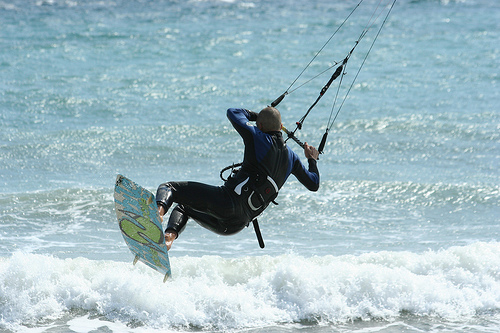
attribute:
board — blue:
[106, 153, 182, 290]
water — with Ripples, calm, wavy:
[361, 110, 478, 222]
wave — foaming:
[288, 245, 488, 322]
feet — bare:
[155, 203, 178, 262]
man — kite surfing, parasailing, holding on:
[153, 95, 330, 256]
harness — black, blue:
[226, 153, 286, 227]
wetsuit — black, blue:
[155, 111, 326, 232]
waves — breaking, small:
[188, 258, 497, 332]